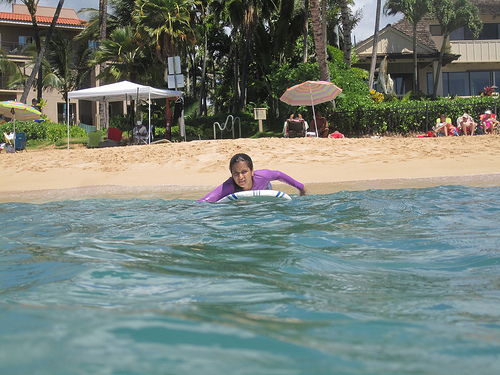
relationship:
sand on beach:
[1, 147, 147, 182] [19, 136, 490, 191]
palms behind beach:
[97, 16, 337, 144] [19, 136, 490, 191]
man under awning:
[127, 125, 156, 147] [66, 82, 186, 105]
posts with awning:
[75, 100, 172, 142] [66, 82, 186, 105]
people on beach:
[279, 114, 496, 148] [19, 136, 490, 191]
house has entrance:
[346, 4, 492, 105] [359, 64, 430, 105]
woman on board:
[198, 154, 309, 202] [220, 187, 290, 207]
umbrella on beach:
[273, 77, 329, 136] [19, 136, 490, 191]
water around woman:
[11, 209, 488, 369] [198, 154, 309, 202]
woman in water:
[198, 154, 309, 202] [11, 209, 488, 369]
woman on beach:
[198, 154, 309, 202] [19, 136, 490, 191]